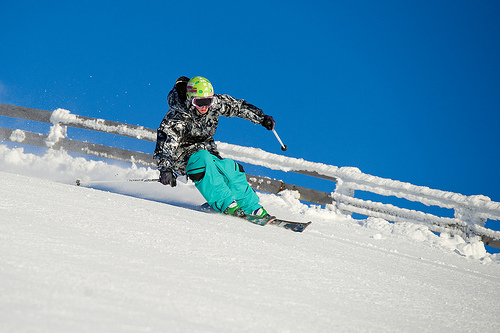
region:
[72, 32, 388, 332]
a person that is skiing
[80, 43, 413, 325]
a person skiing on the snow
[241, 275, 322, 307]
ground covered in snow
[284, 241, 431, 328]
ground covered in white snow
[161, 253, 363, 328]
snow covering the ground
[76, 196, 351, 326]
white snow covering the ground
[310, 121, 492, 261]
snow the railings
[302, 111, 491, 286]
white snow on the railings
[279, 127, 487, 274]
snow on the metal railings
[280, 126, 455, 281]
white snow on the metal railings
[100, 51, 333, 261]
the person is skiing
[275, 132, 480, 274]
the fence is covered with snow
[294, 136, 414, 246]
the fence is covered with snow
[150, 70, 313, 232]
snow skier on the mountainside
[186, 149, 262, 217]
turquoise colored ski pants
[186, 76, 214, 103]
green helmet skier is wearing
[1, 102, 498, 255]
railing with snow on it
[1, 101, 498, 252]
snow sitting on the railing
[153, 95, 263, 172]
black and white jacket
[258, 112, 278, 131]
black glove on left hand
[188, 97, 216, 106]
goggles skier is wearing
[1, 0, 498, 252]
clear blue ski above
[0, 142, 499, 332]
snow covered mountain side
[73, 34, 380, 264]
this person is skiing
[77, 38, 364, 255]
they are speeding down a hill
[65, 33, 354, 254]
this person is skiing down a hill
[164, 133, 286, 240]
their pants are blue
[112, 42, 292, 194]
their jacket is patterned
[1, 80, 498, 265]
a wooden railing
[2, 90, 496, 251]
the fence railing is covered in snow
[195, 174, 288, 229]
their ski boots are green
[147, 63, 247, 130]
their helmet is neon green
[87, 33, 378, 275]
this person is wearing gloves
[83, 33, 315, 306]
a person skiin gont eh snow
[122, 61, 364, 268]
a perosn wearing a helmet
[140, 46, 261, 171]
a person wearing a jacket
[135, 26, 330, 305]
a perosn wearing pants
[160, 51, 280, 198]
a person holding skies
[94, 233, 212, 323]
ground covered in snow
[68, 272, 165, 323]
ground covered in white snow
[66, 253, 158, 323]
snow covering the ground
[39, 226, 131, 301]
white snow covering the ground